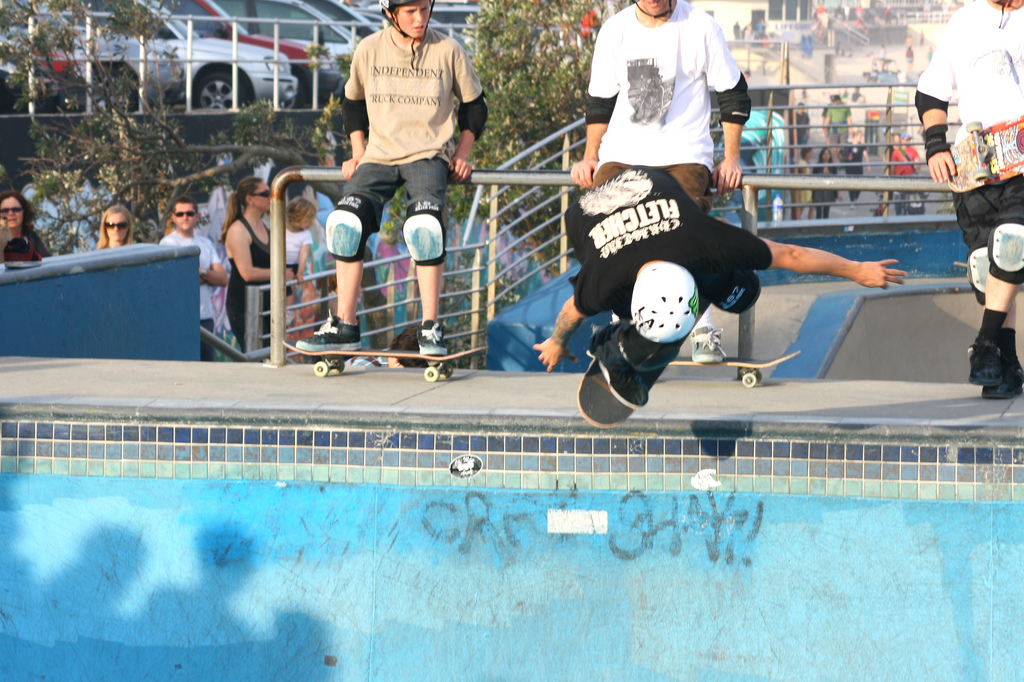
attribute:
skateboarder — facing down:
[519, 155, 909, 400]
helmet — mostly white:
[620, 248, 709, 352]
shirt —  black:
[557, 159, 772, 319]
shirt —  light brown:
[333, 32, 478, 166]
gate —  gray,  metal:
[255, 121, 586, 366]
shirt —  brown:
[337, 28, 489, 176]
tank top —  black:
[214, 213, 281, 294]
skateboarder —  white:
[523, 168, 917, 376]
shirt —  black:
[545, 146, 787, 309]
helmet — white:
[611, 254, 704, 356]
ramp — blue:
[4, 457, 1020, 678]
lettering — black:
[391, 479, 781, 586]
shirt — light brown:
[581, 159, 774, 337]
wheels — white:
[309, 351, 459, 388]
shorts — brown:
[655, 159, 727, 209]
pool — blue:
[0, 457, 1020, 678]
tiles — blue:
[4, 470, 1018, 676]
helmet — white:
[622, 247, 700, 356]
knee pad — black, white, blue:
[400, 206, 455, 274]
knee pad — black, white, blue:
[322, 202, 375, 265]